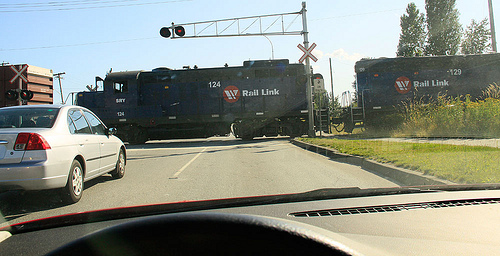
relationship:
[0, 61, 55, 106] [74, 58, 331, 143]
box car pulled by engine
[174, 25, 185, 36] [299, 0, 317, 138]
light on post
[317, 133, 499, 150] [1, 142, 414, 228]
sidewalk next to street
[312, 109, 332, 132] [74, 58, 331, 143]
stair on engine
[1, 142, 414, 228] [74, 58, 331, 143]
street in front of engine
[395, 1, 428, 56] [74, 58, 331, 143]
tree behind engine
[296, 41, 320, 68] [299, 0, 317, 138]
sign on post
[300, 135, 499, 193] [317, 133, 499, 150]
grass next to sidewalk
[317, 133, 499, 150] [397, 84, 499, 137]
sidewalk next to weeds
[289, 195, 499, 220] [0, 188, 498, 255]
vent on dashboard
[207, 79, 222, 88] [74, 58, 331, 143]
number on engine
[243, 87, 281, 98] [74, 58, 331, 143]
lettering on engine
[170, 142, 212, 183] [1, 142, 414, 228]
line in street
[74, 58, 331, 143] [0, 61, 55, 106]
engine pulling box car